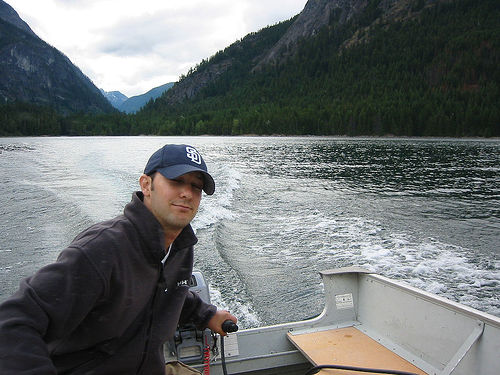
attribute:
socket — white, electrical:
[331, 290, 358, 310]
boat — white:
[188, 270, 500, 375]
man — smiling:
[6, 137, 252, 374]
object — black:
[221, 317, 239, 333]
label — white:
[175, 279, 191, 289]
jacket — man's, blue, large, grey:
[40, 197, 196, 368]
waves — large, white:
[210, 205, 279, 310]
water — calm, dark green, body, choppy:
[210, 142, 497, 278]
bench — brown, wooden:
[292, 333, 410, 374]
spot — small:
[341, 331, 358, 343]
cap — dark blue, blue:
[146, 143, 220, 196]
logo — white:
[183, 146, 205, 166]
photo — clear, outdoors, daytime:
[5, 4, 499, 370]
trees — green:
[163, 94, 477, 136]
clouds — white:
[114, 58, 163, 84]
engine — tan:
[192, 270, 214, 314]